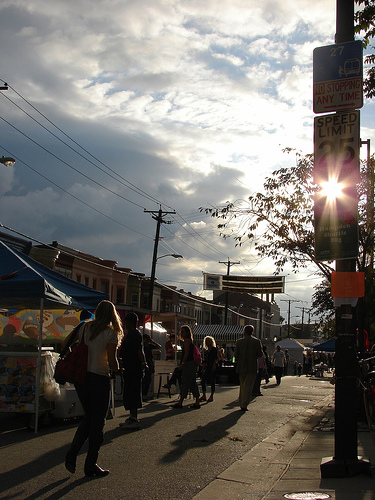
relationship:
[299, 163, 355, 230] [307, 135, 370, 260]
sun on sign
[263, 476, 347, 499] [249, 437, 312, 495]
manhole cover on sidewalk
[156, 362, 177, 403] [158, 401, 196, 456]
stool in street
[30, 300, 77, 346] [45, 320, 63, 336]
sign with icecream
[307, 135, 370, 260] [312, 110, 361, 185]
sign with sign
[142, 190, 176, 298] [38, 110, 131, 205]
poles with wires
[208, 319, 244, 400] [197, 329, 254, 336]
stand with cover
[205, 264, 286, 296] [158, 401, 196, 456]
banner hanging over street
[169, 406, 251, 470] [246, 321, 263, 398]
shadow of man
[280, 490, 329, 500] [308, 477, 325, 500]
manhole cover of manhole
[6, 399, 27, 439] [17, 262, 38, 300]
shade from canopy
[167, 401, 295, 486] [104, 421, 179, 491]
edge of road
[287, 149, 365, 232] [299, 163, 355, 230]
glare from sun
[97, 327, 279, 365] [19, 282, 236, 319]
people at market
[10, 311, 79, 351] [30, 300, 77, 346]
painting on sign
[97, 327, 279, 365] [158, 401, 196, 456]
people in street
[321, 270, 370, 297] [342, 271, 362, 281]
sign with writing